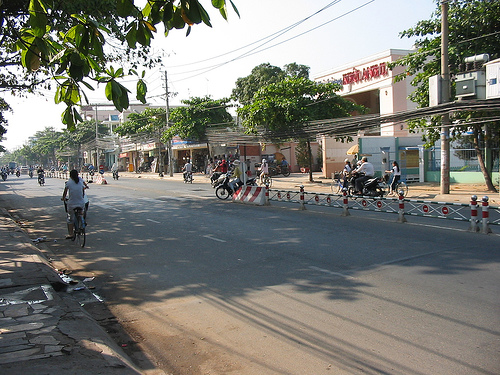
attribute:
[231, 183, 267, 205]
block — red, concrete, white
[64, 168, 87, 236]
person — riding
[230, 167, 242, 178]
shirt — yellow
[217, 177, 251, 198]
moped — black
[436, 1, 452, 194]
pole — tall, brown, wooden, large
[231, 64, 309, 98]
tree — green, tall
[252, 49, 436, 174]
building — tan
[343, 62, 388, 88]
sign — red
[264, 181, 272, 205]
caution pole — red, white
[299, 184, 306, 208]
caution pole — red, white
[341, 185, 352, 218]
caution pole — red, white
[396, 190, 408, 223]
caution pole — red, white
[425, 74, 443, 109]
electrical box — large, square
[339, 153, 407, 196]
group — riding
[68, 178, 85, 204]
shirt — white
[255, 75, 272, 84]
leaves — green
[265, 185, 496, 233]
safety railing — red, white, white black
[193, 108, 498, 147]
electrical wires — thick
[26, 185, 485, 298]
shadows — cast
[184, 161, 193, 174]
shirt — gray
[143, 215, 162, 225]
line — white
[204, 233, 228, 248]
line — white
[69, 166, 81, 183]
hair — brown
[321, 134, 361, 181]
wall — pink